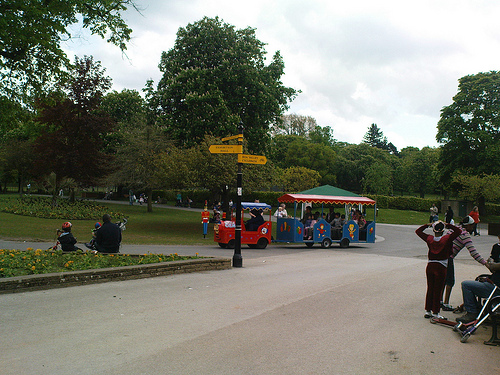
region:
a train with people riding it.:
[213, 180, 390, 250]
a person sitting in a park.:
[85, 210, 145, 270]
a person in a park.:
[48, 218, 90, 262]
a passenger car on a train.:
[279, 185, 388, 250]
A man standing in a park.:
[411, 195, 471, 332]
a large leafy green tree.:
[136, 11, 296, 156]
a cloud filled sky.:
[0, 2, 499, 144]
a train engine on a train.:
[209, 193, 284, 258]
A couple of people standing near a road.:
[405, 203, 472, 320]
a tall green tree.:
[361, 122, 401, 204]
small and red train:
[202, 185, 262, 245]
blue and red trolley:
[287, 187, 379, 255]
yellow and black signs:
[218, 132, 263, 167]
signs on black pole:
[228, 167, 261, 257]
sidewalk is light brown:
[262, 279, 345, 364]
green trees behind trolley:
[0, 37, 321, 239]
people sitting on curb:
[43, 214, 132, 268]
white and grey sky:
[313, 30, 410, 96]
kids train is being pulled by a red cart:
[207, 181, 388, 258]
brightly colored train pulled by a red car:
[216, 178, 381, 253]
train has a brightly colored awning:
[278, 173, 384, 261]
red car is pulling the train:
[218, 174, 382, 258]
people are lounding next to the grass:
[49, 211, 134, 261]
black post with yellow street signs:
[212, 126, 262, 268]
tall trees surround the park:
[1, 5, 499, 220]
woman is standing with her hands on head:
[413, 218, 459, 323]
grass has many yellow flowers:
[3, 238, 205, 286]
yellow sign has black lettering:
[210, 127, 273, 182]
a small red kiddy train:
[191, 211, 276, 245]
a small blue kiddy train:
[275, 206, 373, 256]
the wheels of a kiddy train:
[321, 229, 351, 256]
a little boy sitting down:
[45, 216, 79, 254]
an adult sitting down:
[77, 219, 122, 247]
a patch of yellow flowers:
[25, 249, 56, 269]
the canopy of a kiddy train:
[267, 196, 364, 217]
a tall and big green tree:
[158, 25, 275, 127]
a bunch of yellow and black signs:
[225, 129, 266, 169]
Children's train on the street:
[214, 188, 384, 250]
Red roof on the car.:
[275, 187, 375, 212]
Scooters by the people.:
[426, 280, 497, 343]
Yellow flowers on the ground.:
[0, 241, 79, 276]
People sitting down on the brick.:
[46, 215, 128, 259]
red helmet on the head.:
[55, 219, 75, 236]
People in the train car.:
[296, 203, 370, 242]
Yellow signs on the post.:
[207, 125, 271, 173]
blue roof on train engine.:
[225, 198, 270, 214]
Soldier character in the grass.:
[196, 197, 211, 242]